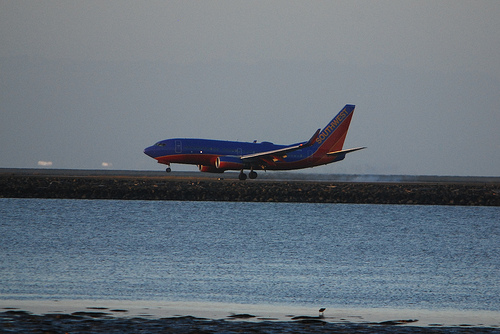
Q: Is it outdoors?
A: Yes, it is outdoors.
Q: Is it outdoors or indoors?
A: It is outdoors.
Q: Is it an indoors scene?
A: No, it is outdoors.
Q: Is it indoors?
A: No, it is outdoors.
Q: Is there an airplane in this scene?
A: Yes, there is an airplane.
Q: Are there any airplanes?
A: Yes, there is an airplane.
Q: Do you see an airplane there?
A: Yes, there is an airplane.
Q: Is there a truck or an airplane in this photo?
A: Yes, there is an airplane.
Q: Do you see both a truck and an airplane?
A: No, there is an airplane but no trucks.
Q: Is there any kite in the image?
A: No, there are no kites.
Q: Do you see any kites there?
A: No, there are no kites.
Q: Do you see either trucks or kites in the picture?
A: No, there are no kites or trucks.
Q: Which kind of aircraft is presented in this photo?
A: The aircraft is an airplane.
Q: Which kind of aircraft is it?
A: The aircraft is an airplane.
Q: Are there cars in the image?
A: No, there are no cars.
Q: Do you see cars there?
A: No, there are no cars.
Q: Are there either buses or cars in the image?
A: No, there are no cars or buses.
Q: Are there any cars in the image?
A: No, there are no cars.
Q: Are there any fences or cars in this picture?
A: No, there are no cars or fences.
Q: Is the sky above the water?
A: Yes, the sky is above the water.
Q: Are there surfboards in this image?
A: No, there are no surfboards.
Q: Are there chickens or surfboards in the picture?
A: No, there are no surfboards or chickens.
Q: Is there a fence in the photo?
A: No, there are no fences.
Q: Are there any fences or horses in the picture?
A: No, there are no fences or horses.